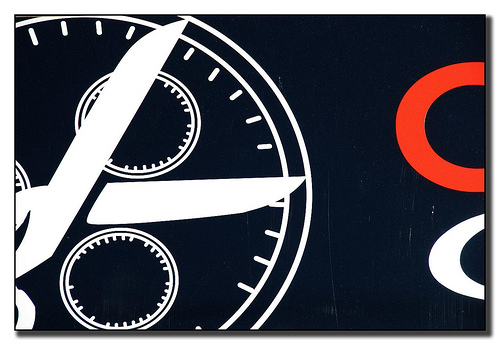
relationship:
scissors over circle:
[13, 18, 306, 329] [207, 22, 324, 147]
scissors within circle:
[13, 18, 306, 329] [12, 22, 324, 333]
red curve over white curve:
[385, 54, 485, 195] [426, 211, 483, 306]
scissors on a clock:
[13, 18, 306, 329] [20, 18, 317, 333]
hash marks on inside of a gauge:
[89, 75, 192, 170] [12, 16, 323, 330]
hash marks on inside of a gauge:
[14, 17, 286, 329] [12, 16, 323, 330]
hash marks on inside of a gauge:
[64, 230, 171, 327] [12, 16, 323, 330]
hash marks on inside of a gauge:
[13, 167, 23, 191] [12, 16, 323, 330]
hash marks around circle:
[64, 230, 171, 327] [57, 226, 179, 344]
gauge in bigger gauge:
[12, 48, 322, 330] [52, 227, 179, 331]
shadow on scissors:
[81, 179, 106, 226] [13, 18, 306, 329]